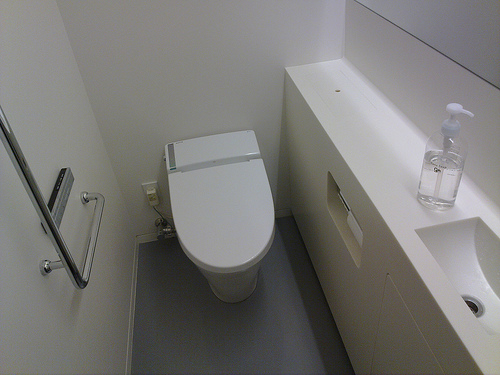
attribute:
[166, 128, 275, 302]
toilet — white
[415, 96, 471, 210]
bottle of soap — clear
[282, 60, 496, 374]
counter — white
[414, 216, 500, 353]
sink — white, curved, narrow, rectangular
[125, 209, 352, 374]
floor — grey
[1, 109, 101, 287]
chrome bar — for safety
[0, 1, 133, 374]
wall — grey, gray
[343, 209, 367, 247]
toilet roll — white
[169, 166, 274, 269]
toilet seat lid — down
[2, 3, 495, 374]
bathroom — narrow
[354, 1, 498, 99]
line — dark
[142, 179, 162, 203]
outlet — plug in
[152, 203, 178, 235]
wire — dark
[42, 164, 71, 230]
deodorizer — electric